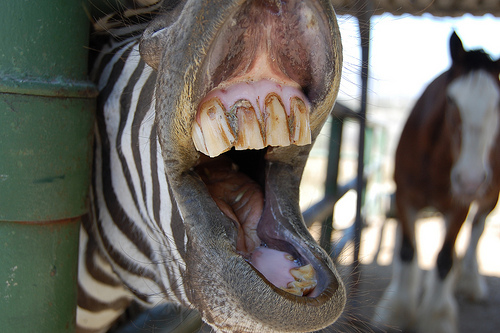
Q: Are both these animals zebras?
A: No, they are horses and zebras.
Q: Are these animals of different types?
A: Yes, they are horses and zebras.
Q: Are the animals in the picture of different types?
A: Yes, they are horses and zebras.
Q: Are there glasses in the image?
A: No, there are no glasses.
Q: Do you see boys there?
A: No, there are no boys.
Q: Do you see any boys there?
A: No, there are no boys.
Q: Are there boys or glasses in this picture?
A: No, there are no boys or glasses.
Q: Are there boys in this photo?
A: No, there are no boys.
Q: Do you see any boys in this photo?
A: No, there are no boys.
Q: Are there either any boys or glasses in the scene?
A: No, there are no boys or glasses.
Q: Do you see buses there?
A: No, there are no buses.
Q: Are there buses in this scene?
A: No, there are no buses.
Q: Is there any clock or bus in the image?
A: No, there are no buses or clocks.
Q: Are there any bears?
A: No, there are no bears.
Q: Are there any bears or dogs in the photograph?
A: No, there are no bears or dogs.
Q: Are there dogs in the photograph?
A: No, there are no dogs.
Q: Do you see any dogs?
A: No, there are no dogs.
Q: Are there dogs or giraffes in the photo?
A: No, there are no dogs or giraffes.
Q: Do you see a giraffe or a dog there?
A: No, there are no dogs or giraffes.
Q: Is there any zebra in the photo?
A: Yes, there is a zebra.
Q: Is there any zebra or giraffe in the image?
A: Yes, there is a zebra.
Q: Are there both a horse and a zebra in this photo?
A: Yes, there are both a zebra and a horse.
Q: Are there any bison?
A: No, there are no bison.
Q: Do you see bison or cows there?
A: No, there are no bison or cows.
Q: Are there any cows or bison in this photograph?
A: No, there are no bison or cows.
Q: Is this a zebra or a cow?
A: This is a zebra.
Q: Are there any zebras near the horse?
A: Yes, there is a zebra near the horse.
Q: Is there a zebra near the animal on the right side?
A: Yes, there is a zebra near the horse.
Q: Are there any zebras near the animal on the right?
A: Yes, there is a zebra near the horse.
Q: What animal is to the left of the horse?
A: The animal is a zebra.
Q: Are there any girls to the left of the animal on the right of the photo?
A: No, there is a zebra to the left of the horse.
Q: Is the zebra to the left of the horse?
A: Yes, the zebra is to the left of the horse.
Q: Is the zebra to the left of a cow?
A: No, the zebra is to the left of the horse.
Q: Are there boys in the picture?
A: No, there are no boys.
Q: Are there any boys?
A: No, there are no boys.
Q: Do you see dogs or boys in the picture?
A: No, there are no boys or dogs.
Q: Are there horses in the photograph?
A: Yes, there is a horse.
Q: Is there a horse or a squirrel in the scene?
A: Yes, there is a horse.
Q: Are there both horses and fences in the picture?
A: Yes, there are both a horse and a fence.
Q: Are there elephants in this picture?
A: No, there are no elephants.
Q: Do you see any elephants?
A: No, there are no elephants.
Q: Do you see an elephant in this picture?
A: No, there are no elephants.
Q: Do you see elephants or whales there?
A: No, there are no elephants or whales.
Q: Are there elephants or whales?
A: No, there are no elephants or whales.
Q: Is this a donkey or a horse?
A: This is a horse.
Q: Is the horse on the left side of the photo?
A: No, the horse is on the right of the image.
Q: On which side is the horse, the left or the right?
A: The horse is on the right of the image.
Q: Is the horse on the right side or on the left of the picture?
A: The horse is on the right of the image.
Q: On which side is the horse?
A: The horse is on the right of the image.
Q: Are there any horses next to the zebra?
A: Yes, there is a horse next to the zebra.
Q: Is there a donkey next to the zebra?
A: No, there is a horse next to the zebra.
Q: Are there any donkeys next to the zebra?
A: No, there is a horse next to the zebra.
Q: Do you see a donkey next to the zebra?
A: No, there is a horse next to the zebra.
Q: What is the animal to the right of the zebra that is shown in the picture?
A: The animal is a horse.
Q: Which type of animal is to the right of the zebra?
A: The animal is a horse.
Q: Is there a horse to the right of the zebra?
A: Yes, there is a horse to the right of the zebra.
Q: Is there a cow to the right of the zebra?
A: No, there is a horse to the right of the zebra.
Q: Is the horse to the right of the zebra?
A: Yes, the horse is to the right of the zebra.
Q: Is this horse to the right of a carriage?
A: No, the horse is to the right of the zebra.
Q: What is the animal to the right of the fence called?
A: The animal is a horse.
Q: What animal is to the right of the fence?
A: The animal is a horse.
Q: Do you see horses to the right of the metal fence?
A: Yes, there is a horse to the right of the fence.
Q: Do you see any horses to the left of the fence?
A: No, the horse is to the right of the fence.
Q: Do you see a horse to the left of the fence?
A: No, the horse is to the right of the fence.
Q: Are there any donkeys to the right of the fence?
A: No, there is a horse to the right of the fence.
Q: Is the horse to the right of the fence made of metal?
A: Yes, the horse is to the right of the fence.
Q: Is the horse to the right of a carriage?
A: No, the horse is to the right of the fence.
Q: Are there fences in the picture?
A: Yes, there is a fence.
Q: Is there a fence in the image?
A: Yes, there is a fence.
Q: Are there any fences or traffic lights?
A: Yes, there is a fence.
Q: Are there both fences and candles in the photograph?
A: No, there is a fence but no candles.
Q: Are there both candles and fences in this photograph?
A: No, there is a fence but no candles.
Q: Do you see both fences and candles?
A: No, there is a fence but no candles.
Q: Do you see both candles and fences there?
A: No, there is a fence but no candles.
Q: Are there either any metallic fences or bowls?
A: Yes, there is a metal fence.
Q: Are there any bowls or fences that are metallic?
A: Yes, the fence is metallic.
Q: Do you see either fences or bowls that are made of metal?
A: Yes, the fence is made of metal.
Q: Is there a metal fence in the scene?
A: Yes, there is a metal fence.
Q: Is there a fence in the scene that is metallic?
A: Yes, there is a fence that is metallic.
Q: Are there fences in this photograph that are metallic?
A: Yes, there is a fence that is metallic.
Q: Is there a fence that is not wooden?
A: Yes, there is a metallic fence.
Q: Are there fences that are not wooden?
A: Yes, there is a metallic fence.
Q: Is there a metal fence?
A: Yes, there is a fence that is made of metal.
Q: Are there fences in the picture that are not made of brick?
A: Yes, there is a fence that is made of metal.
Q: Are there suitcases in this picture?
A: No, there are no suitcases.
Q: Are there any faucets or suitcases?
A: No, there are no suitcases or faucets.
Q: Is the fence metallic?
A: Yes, the fence is metallic.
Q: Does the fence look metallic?
A: Yes, the fence is metallic.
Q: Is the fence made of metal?
A: Yes, the fence is made of metal.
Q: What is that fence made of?
A: The fence is made of metal.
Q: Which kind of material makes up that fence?
A: The fence is made of metal.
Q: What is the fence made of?
A: The fence is made of metal.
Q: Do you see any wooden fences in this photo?
A: No, there is a fence but it is metallic.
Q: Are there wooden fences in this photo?
A: No, there is a fence but it is metallic.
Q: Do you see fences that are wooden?
A: No, there is a fence but it is metallic.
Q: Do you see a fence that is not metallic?
A: No, there is a fence but it is metallic.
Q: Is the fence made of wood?
A: No, the fence is made of metal.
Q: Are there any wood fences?
A: No, there is a fence but it is made of metal.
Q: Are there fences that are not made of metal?
A: No, there is a fence but it is made of metal.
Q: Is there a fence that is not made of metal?
A: No, there is a fence but it is made of metal.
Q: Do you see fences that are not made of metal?
A: No, there is a fence but it is made of metal.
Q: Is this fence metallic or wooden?
A: The fence is metallic.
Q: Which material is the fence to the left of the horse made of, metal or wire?
A: The fence is made of metal.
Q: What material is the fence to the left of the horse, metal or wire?
A: The fence is made of metal.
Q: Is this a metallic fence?
A: Yes, this is a metallic fence.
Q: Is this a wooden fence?
A: No, this is a metallic fence.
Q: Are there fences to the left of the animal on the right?
A: Yes, there is a fence to the left of the horse.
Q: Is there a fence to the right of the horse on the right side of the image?
A: No, the fence is to the left of the horse.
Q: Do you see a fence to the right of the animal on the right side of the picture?
A: No, the fence is to the left of the horse.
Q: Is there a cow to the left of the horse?
A: No, there is a fence to the left of the horse.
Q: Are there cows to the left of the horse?
A: No, there is a fence to the left of the horse.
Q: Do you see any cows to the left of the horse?
A: No, there is a fence to the left of the horse.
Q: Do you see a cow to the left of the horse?
A: No, there is a fence to the left of the horse.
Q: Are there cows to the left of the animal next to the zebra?
A: No, there is a fence to the left of the horse.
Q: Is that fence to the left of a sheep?
A: No, the fence is to the left of the horse.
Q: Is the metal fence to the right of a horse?
A: No, the fence is to the left of a horse.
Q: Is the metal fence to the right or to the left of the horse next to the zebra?
A: The fence is to the left of the horse.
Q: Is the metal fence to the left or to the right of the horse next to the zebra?
A: The fence is to the left of the horse.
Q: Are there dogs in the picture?
A: No, there are no dogs.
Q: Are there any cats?
A: No, there are no cats.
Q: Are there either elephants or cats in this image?
A: No, there are no cats or elephants.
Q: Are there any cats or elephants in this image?
A: No, there are no cats or elephants.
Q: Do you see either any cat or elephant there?
A: No, there are no cats or elephants.